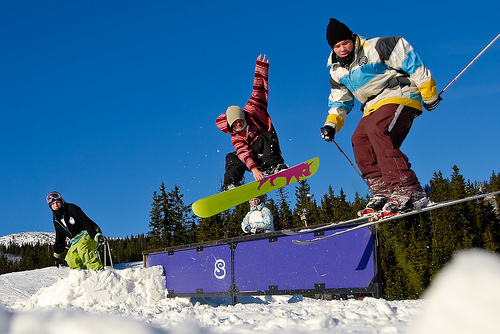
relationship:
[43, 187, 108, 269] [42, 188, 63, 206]
skier wearing goggles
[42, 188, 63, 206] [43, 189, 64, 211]
goggles on head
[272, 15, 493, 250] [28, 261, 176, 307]
skier jumping ramp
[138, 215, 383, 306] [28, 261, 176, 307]
fence by ramp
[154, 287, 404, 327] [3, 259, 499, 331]
prints in snow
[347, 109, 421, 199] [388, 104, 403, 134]
pants have stripe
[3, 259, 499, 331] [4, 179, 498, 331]
snow on mountain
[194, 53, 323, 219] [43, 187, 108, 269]
snowboarder with skier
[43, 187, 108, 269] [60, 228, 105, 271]
skier wearing pants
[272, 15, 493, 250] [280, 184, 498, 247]
skier on skis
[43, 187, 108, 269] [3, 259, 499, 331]
skier in snow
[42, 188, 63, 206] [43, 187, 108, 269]
goggles on skier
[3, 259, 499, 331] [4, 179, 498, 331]
snow covered mountain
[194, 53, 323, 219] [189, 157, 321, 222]
snowboarder on snowboard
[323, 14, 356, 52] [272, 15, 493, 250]
cap on skier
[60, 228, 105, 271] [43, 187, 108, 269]
pants on skier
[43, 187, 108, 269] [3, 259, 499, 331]
skier on snow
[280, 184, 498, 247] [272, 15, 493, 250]
skis on skier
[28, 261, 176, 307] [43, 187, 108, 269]
ramp in front of skier